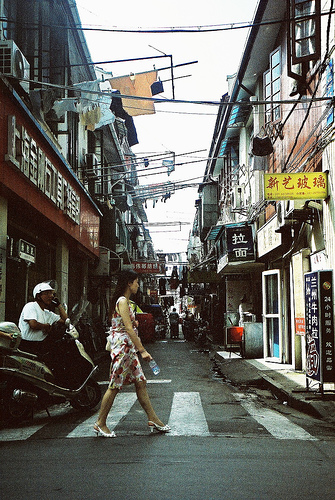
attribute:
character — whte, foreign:
[309, 273, 317, 287]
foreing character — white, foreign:
[322, 325, 332, 334]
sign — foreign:
[308, 271, 318, 288]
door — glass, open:
[253, 268, 295, 365]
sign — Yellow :
[263, 170, 330, 202]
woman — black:
[104, 257, 152, 367]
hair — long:
[112, 266, 134, 302]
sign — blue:
[296, 271, 327, 371]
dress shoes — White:
[87, 418, 172, 440]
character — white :
[311, 316, 318, 328]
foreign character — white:
[306, 278, 316, 360]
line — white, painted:
[166, 386, 211, 436]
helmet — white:
[30, 282, 54, 297]